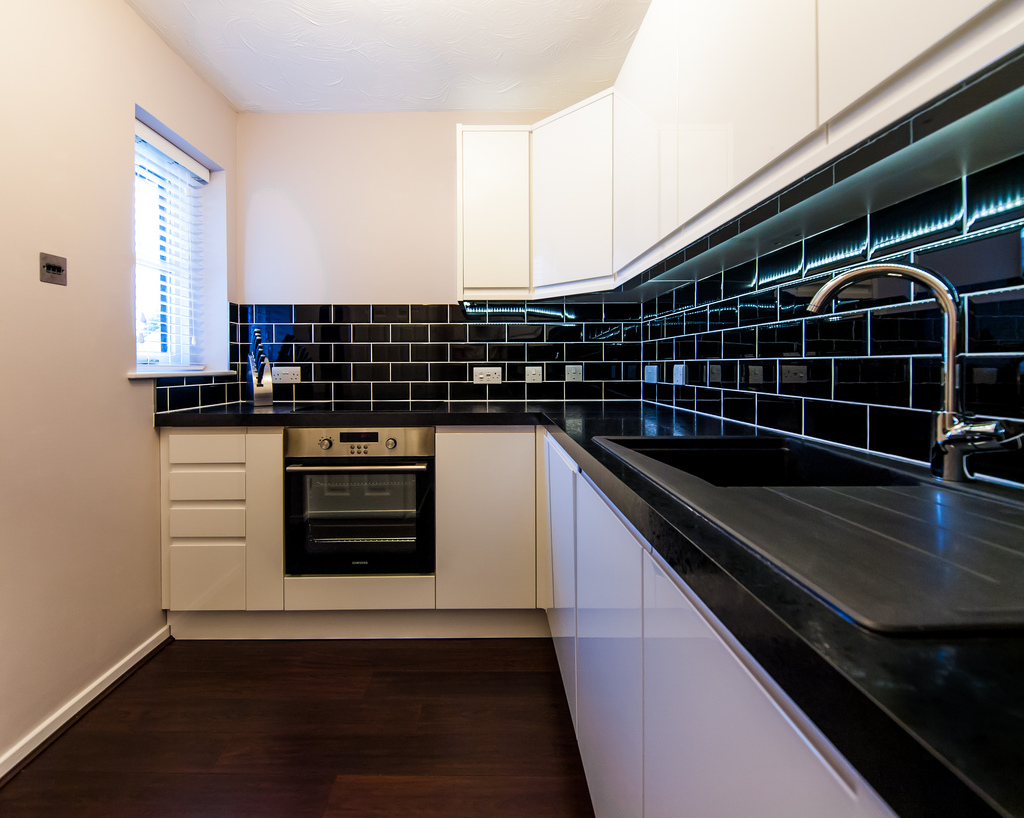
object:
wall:
[0, 0, 236, 771]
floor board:
[0, 623, 171, 771]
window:
[134, 136, 190, 366]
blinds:
[135, 134, 206, 370]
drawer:
[168, 432, 246, 537]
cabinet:
[435, 425, 535, 609]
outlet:
[473, 367, 501, 385]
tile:
[565, 365, 582, 381]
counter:
[151, 402, 1024, 818]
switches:
[46, 264, 61, 274]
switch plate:
[40, 252, 67, 286]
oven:
[283, 427, 436, 576]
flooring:
[0, 638, 595, 816]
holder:
[248, 354, 273, 406]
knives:
[252, 329, 266, 387]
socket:
[272, 366, 301, 383]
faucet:
[806, 263, 1023, 483]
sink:
[604, 437, 923, 488]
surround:
[592, 435, 1024, 681]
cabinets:
[455, 0, 1024, 301]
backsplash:
[155, 45, 1022, 497]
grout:
[154, 45, 1024, 503]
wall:
[233, 111, 458, 304]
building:
[0, 0, 1024, 818]